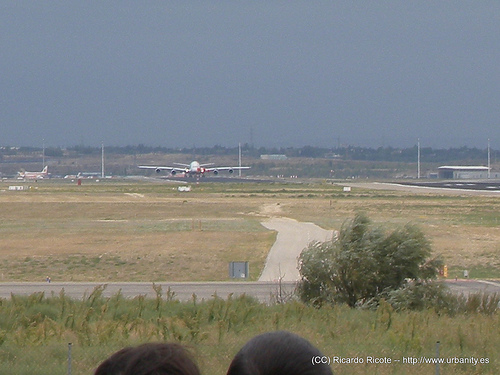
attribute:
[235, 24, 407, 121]
sky — overcast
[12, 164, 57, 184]
aircraft — small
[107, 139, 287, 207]
plane — distant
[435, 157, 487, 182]
hangar — pictured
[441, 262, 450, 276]
pole — yellow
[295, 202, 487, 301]
tree — windblown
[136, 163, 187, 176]
wing —    plane's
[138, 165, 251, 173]
wings — large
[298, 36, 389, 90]
sky —   gray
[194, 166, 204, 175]
tail — red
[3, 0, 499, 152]
sky — overcast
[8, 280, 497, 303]
runway side — bushy